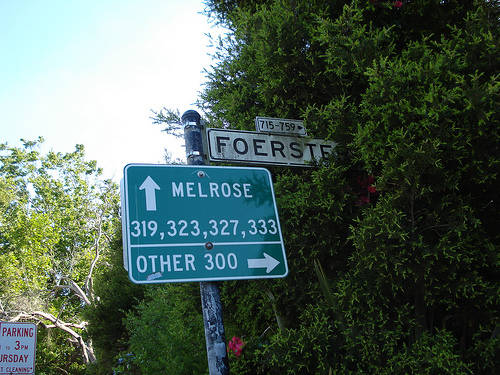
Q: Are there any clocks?
A: No, there are no clocks.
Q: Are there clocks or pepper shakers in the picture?
A: No, there are no clocks or pepper shakers.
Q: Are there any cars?
A: No, there are no cars.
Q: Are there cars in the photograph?
A: No, there are no cars.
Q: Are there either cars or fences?
A: No, there are no cars or fences.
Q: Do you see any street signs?
A: Yes, there is a street sign.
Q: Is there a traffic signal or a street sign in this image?
A: Yes, there is a street sign.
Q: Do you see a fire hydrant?
A: No, there are no fire hydrants.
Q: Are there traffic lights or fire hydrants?
A: No, there are no fire hydrants or traffic lights.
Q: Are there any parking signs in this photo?
A: Yes, there is a parking sign.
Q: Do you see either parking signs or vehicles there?
A: Yes, there is a parking sign.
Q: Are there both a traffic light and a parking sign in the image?
A: No, there is a parking sign but no traffic lights.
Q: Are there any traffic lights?
A: No, there are no traffic lights.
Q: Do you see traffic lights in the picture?
A: No, there are no traffic lights.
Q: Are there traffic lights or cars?
A: No, there are no traffic lights or cars.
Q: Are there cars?
A: No, there are no cars.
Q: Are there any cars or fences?
A: No, there are no cars or fences.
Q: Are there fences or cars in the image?
A: No, there are no cars or fences.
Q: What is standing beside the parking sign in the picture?
A: The tree is standing beside the parking sign.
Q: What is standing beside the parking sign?
A: The tree is standing beside the parking sign.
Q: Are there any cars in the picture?
A: No, there are no cars.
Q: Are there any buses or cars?
A: No, there are no cars or buses.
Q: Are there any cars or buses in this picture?
A: No, there are no cars or buses.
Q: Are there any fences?
A: No, there are no fences.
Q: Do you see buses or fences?
A: No, there are no fences or buses.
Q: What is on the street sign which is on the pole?
A: The arrow is on the street sign.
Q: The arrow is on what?
A: The arrow is on the street sign.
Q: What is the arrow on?
A: The arrow is on the street sign.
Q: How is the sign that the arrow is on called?
A: The sign is a street sign.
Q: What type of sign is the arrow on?
A: The arrow is on the street sign.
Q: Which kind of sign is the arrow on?
A: The arrow is on the street sign.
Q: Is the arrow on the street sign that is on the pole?
A: Yes, the arrow is on the street sign.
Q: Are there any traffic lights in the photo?
A: No, there are no traffic lights.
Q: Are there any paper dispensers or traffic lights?
A: No, there are no traffic lights or paper dispensers.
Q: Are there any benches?
A: No, there are no benches.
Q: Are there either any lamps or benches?
A: No, there are no benches or lamps.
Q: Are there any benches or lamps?
A: No, there are no benches or lamps.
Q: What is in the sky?
A: The clouds are in the sky.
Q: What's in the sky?
A: The clouds are in the sky.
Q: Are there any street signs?
A: Yes, there is a street sign.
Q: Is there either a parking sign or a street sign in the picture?
A: Yes, there is a street sign.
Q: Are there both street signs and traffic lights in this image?
A: No, there is a street sign but no traffic lights.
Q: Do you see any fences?
A: No, there are no fences.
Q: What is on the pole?
A: The street sign is on the pole.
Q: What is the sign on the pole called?
A: The sign is a street sign.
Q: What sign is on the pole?
A: The sign is a street sign.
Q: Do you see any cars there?
A: No, there are no cars.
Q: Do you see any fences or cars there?
A: No, there are no cars or fences.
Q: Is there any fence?
A: No, there are no fences.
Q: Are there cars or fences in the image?
A: No, there are no fences or cars.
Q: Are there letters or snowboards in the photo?
A: Yes, there are letters.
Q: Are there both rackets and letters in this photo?
A: No, there are letters but no rackets.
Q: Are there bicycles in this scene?
A: No, there are no bicycles.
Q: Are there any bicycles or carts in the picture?
A: No, there are no bicycles or carts.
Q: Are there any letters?
A: Yes, there are letters.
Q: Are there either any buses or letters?
A: Yes, there are letters.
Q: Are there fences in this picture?
A: No, there are no fences.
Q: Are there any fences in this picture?
A: No, there are no fences.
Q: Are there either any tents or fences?
A: No, there are no fences or tents.